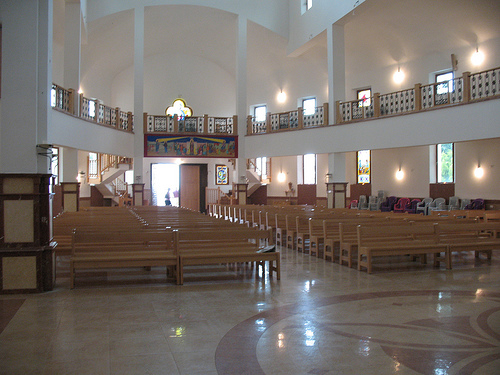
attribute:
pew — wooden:
[72, 235, 284, 273]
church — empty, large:
[5, 8, 495, 372]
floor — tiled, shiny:
[16, 286, 499, 371]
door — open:
[152, 166, 181, 207]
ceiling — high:
[67, 3, 474, 69]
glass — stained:
[440, 149, 452, 182]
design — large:
[222, 288, 499, 374]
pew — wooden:
[56, 217, 231, 224]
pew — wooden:
[341, 224, 353, 264]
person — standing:
[164, 187, 170, 204]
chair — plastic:
[431, 196, 448, 211]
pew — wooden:
[307, 217, 322, 260]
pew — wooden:
[282, 212, 297, 248]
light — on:
[275, 171, 289, 184]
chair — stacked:
[370, 192, 382, 211]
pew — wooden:
[221, 203, 231, 220]